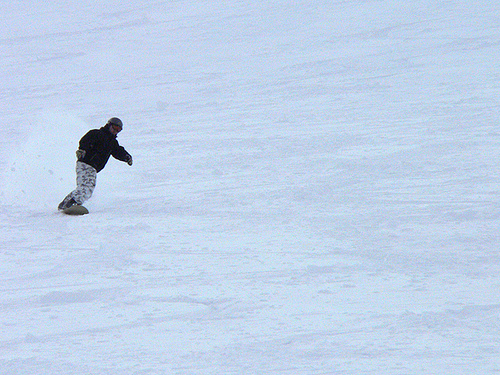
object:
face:
[109, 123, 122, 135]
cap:
[105, 116, 123, 129]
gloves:
[125, 154, 133, 166]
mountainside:
[7, 8, 499, 373]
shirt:
[80, 126, 130, 173]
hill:
[4, 2, 499, 372]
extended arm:
[112, 138, 134, 167]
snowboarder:
[33, 106, 143, 227]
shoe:
[60, 202, 90, 215]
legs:
[64, 160, 97, 206]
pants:
[59, 161, 97, 206]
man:
[57, 116, 134, 215]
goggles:
[108, 123, 121, 133]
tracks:
[12, 202, 160, 264]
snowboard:
[53, 201, 89, 216]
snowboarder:
[47, 111, 142, 218]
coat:
[78, 127, 133, 173]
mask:
[108, 123, 122, 137]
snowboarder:
[64, 114, 134, 212]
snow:
[9, 7, 493, 369]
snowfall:
[2, 0, 499, 373]